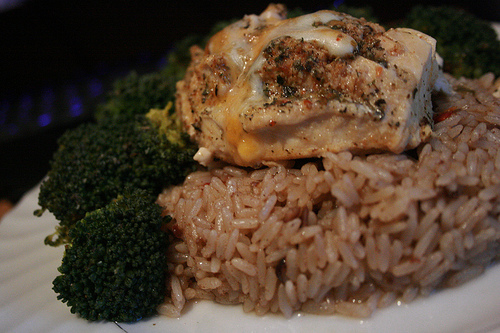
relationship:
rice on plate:
[156, 70, 499, 318] [1, 170, 499, 331]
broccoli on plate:
[34, 3, 500, 324] [1, 170, 499, 331]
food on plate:
[35, 4, 500, 322] [1, 170, 499, 331]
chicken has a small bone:
[173, 2, 453, 168] [192, 3, 288, 169]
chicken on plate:
[173, 2, 453, 168] [1, 170, 499, 331]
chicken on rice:
[173, 2, 453, 168] [156, 70, 499, 318]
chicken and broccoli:
[173, 2, 453, 168] [34, 3, 500, 324]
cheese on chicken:
[196, 2, 360, 164] [173, 2, 453, 168]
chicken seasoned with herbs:
[173, 2, 453, 168] [172, 3, 454, 167]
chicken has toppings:
[173, 2, 453, 168] [178, 3, 453, 163]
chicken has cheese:
[173, 2, 453, 168] [196, 2, 360, 164]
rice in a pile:
[156, 70, 499, 318] [156, 73, 500, 318]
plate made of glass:
[1, 170, 499, 331] [0, 173, 500, 332]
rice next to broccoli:
[156, 70, 499, 318] [34, 3, 500, 324]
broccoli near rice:
[34, 3, 500, 324] [156, 70, 499, 318]